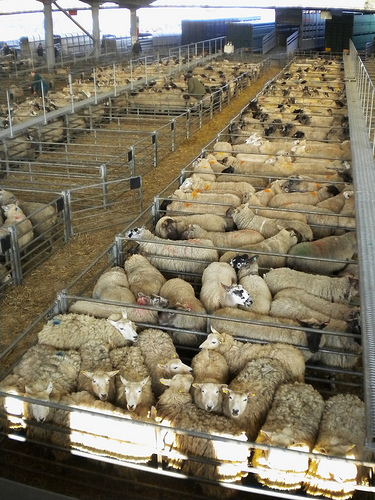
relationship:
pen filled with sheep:
[99, 251, 362, 341] [117, 229, 306, 322]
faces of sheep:
[230, 245, 255, 301] [117, 229, 306, 322]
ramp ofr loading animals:
[263, 33, 296, 56] [196, 181, 358, 399]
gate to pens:
[60, 183, 148, 252] [31, 90, 191, 210]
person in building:
[31, 67, 52, 105] [23, 12, 374, 253]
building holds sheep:
[23, 12, 374, 253] [117, 229, 306, 322]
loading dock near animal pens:
[185, 21, 364, 51] [176, 45, 354, 120]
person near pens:
[31, 67, 52, 105] [31, 90, 191, 210]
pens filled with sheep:
[31, 90, 191, 210] [117, 229, 306, 322]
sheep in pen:
[117, 229, 306, 322] [99, 251, 362, 341]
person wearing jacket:
[31, 67, 52, 90] [30, 74, 53, 92]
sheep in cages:
[117, 229, 306, 322] [147, 92, 354, 338]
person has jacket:
[31, 67, 52, 105] [40, 84, 52, 93]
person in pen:
[31, 67, 52, 105] [0, 33, 89, 124]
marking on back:
[185, 186, 200, 201] [176, 165, 236, 219]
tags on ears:
[192, 192, 202, 202] [191, 188, 205, 202]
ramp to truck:
[263, 33, 296, 56] [271, 11, 335, 51]